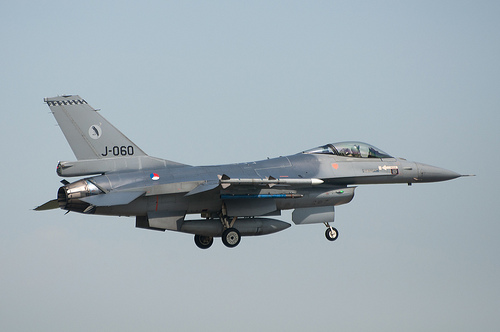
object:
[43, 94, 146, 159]
tail wing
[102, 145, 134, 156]
id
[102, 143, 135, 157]
writings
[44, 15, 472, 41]
air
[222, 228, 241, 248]
wheel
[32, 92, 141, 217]
tail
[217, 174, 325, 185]
missile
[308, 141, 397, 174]
pilot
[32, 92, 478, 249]
plane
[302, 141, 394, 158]
cockpit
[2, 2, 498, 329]
sky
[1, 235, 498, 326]
cloud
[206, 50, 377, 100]
cloud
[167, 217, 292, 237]
missile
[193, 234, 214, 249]
wheels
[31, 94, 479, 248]
fighter jet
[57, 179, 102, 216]
engine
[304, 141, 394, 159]
window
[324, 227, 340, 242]
wheel